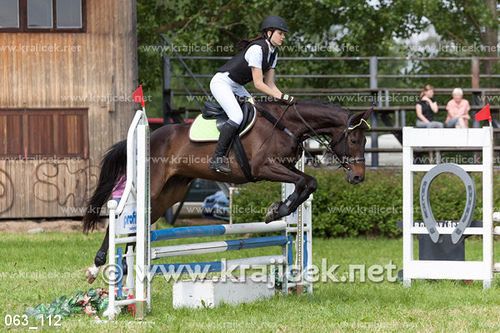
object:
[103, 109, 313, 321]
fence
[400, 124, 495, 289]
fence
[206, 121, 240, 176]
boot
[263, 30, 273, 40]
ear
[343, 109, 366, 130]
ear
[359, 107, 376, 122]
ear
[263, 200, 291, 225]
hoof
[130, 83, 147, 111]
flag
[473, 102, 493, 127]
flag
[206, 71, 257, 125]
pants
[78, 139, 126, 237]
tail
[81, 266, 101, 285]
hoof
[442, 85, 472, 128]
people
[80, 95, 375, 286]
horse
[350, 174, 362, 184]
nose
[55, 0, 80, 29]
window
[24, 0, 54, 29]
window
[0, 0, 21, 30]
window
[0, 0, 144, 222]
building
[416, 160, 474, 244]
horseshoe sign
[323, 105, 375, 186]
head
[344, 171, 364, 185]
mouth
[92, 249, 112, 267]
hoof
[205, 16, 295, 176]
rider